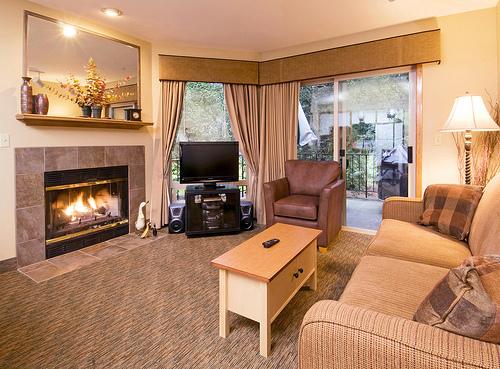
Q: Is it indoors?
A: Yes, it is indoors.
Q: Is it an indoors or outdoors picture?
A: It is indoors.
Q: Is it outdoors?
A: No, it is indoors.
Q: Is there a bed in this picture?
A: No, there are no beds.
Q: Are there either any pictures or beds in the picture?
A: No, there are no beds or pictures.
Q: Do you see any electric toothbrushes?
A: No, there are no electric toothbrushes.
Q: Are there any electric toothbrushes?
A: No, there are no electric toothbrushes.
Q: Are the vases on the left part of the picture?
A: Yes, the vases are on the left of the image.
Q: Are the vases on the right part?
A: No, the vases are on the left of the image.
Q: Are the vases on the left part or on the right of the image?
A: The vases are on the left of the image.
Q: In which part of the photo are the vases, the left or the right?
A: The vases are on the left of the image.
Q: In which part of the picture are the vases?
A: The vases are on the left of the image.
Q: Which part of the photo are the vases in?
A: The vases are on the left of the image.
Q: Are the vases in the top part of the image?
A: Yes, the vases are in the top of the image.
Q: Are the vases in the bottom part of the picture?
A: No, the vases are in the top of the image.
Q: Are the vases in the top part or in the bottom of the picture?
A: The vases are in the top of the image.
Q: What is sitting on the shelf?
A: The vases are sitting on the shelf.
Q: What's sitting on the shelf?
A: The vases are sitting on the shelf.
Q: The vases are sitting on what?
A: The vases are sitting on the shelf.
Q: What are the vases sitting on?
A: The vases are sitting on the shelf.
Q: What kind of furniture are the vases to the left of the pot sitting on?
A: The vases are sitting on the shelf.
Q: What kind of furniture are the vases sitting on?
A: The vases are sitting on the shelf.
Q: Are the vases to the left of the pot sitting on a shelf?
A: Yes, the vases are sitting on a shelf.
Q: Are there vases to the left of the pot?
A: Yes, there are vases to the left of the pot.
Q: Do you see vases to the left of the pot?
A: Yes, there are vases to the left of the pot.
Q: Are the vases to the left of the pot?
A: Yes, the vases are to the left of the pot.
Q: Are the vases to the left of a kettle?
A: No, the vases are to the left of the pot.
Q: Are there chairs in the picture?
A: Yes, there is a chair.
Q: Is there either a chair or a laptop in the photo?
A: Yes, there is a chair.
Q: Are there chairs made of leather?
A: Yes, there is a chair that is made of leather.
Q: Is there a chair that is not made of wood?
A: Yes, there is a chair that is made of leather.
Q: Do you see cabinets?
A: No, there are no cabinets.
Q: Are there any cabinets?
A: No, there are no cabinets.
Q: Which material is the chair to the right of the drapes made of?
A: The chair is made of leather.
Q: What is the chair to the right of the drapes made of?
A: The chair is made of leather.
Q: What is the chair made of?
A: The chair is made of leather.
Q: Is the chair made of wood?
A: No, the chair is made of leather.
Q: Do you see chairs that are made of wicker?
A: No, there is a chair but it is made of leather.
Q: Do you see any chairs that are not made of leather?
A: No, there is a chair but it is made of leather.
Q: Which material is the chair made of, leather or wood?
A: The chair is made of leather.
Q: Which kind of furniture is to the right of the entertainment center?
A: The piece of furniture is a chair.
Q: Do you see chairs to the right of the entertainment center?
A: Yes, there is a chair to the right of the entertainment center.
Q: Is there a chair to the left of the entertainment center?
A: No, the chair is to the right of the entertainment center.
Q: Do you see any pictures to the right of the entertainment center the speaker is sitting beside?
A: No, there is a chair to the right of the entertainment center.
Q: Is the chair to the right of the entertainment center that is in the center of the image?
A: Yes, the chair is to the right of the entertainment center.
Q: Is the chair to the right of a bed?
A: No, the chair is to the right of the entertainment center.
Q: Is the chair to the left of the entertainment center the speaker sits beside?
A: No, the chair is to the right of the entertainment center.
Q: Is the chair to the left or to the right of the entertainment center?
A: The chair is to the right of the entertainment center.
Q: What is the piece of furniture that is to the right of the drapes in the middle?
A: The piece of furniture is a chair.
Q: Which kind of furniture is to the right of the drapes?
A: The piece of furniture is a chair.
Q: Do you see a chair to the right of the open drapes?
A: Yes, there is a chair to the right of the drapes.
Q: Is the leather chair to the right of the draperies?
A: Yes, the chair is to the right of the draperies.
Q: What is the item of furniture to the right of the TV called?
A: The piece of furniture is a chair.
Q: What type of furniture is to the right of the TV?
A: The piece of furniture is a chair.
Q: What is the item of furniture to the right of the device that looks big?
A: The piece of furniture is a chair.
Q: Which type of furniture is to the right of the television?
A: The piece of furniture is a chair.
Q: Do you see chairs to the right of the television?
A: Yes, there is a chair to the right of the television.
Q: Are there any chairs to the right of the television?
A: Yes, there is a chair to the right of the television.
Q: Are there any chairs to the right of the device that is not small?
A: Yes, there is a chair to the right of the television.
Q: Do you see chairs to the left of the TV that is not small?
A: No, the chair is to the right of the TV.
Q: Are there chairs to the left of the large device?
A: No, the chair is to the right of the TV.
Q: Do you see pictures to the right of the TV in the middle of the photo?
A: No, there is a chair to the right of the TV.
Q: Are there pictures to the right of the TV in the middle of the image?
A: No, there is a chair to the right of the TV.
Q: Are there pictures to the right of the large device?
A: No, there is a chair to the right of the TV.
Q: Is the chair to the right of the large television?
A: Yes, the chair is to the right of the TV.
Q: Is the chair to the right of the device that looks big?
A: Yes, the chair is to the right of the TV.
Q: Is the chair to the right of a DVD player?
A: No, the chair is to the right of the TV.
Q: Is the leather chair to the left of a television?
A: No, the chair is to the right of a television.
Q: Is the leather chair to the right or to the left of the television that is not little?
A: The chair is to the right of the television.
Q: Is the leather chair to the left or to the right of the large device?
A: The chair is to the right of the television.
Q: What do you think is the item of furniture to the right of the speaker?
A: The piece of furniture is a chair.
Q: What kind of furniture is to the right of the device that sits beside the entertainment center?
A: The piece of furniture is a chair.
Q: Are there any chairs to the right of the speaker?
A: Yes, there is a chair to the right of the speaker.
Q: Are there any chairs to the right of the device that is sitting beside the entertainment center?
A: Yes, there is a chair to the right of the speaker.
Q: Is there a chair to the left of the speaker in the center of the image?
A: No, the chair is to the right of the speaker.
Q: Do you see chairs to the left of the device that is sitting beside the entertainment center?
A: No, the chair is to the right of the speaker.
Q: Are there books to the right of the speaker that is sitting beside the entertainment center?
A: No, there is a chair to the right of the speaker.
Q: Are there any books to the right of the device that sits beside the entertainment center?
A: No, there is a chair to the right of the speaker.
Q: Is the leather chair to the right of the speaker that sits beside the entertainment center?
A: Yes, the chair is to the right of the speaker.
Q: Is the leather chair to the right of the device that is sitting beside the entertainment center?
A: Yes, the chair is to the right of the speaker.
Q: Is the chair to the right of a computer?
A: No, the chair is to the right of the speaker.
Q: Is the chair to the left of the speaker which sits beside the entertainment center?
A: No, the chair is to the right of the speaker.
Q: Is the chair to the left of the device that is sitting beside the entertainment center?
A: No, the chair is to the right of the speaker.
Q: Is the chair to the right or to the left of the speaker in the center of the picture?
A: The chair is to the right of the speaker.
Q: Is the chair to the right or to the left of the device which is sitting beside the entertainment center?
A: The chair is to the right of the speaker.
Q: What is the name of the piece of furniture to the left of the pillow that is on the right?
A: The piece of furniture is a chair.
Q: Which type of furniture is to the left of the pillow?
A: The piece of furniture is a chair.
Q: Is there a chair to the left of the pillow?
A: Yes, there is a chair to the left of the pillow.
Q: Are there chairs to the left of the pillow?
A: Yes, there is a chair to the left of the pillow.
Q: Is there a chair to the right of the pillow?
A: No, the chair is to the left of the pillow.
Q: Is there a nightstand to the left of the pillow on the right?
A: No, there is a chair to the left of the pillow.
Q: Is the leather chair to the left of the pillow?
A: Yes, the chair is to the left of the pillow.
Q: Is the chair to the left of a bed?
A: No, the chair is to the left of the pillow.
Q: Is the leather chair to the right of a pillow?
A: No, the chair is to the left of a pillow.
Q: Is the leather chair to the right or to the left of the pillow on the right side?
A: The chair is to the left of the pillow.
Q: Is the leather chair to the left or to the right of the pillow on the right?
A: The chair is to the left of the pillow.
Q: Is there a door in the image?
A: Yes, there are doors.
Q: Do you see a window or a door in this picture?
A: Yes, there are doors.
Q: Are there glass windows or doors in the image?
A: Yes, there are glass doors.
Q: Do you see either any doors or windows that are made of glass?
A: Yes, the doors are made of glass.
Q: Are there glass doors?
A: Yes, there are doors that are made of glass.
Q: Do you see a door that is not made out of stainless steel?
A: Yes, there are doors that are made of glass.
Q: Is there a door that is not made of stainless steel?
A: Yes, there are doors that are made of glass.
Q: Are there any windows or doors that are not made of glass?
A: No, there are doors but they are made of glass.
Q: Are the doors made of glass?
A: Yes, the doors are made of glass.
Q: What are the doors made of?
A: The doors are made of glass.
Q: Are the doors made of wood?
A: No, the doors are made of glass.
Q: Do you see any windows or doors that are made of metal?
A: No, there are doors but they are made of glass.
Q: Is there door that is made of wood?
A: No, there are doors but they are made of glass.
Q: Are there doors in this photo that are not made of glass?
A: No, there are doors but they are made of glass.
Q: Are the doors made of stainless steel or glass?
A: The doors are made of glass.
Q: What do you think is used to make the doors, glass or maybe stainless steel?
A: The doors are made of glass.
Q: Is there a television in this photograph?
A: Yes, there is a television.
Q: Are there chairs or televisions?
A: Yes, there is a television.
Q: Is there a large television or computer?
A: Yes, there is a large television.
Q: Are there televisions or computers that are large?
A: Yes, the television is large.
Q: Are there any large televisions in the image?
A: Yes, there is a large television.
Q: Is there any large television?
A: Yes, there is a large television.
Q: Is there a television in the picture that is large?
A: Yes, there is a television that is large.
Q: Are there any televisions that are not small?
A: Yes, there is a large television.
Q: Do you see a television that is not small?
A: Yes, there is a large television.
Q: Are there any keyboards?
A: No, there are no keyboards.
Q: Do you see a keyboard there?
A: No, there are no keyboards.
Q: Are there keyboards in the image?
A: No, there are no keyboards.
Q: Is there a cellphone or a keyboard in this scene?
A: No, there are no keyboards or cell phones.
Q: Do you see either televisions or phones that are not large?
A: No, there is a television but it is large.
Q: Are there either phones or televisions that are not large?
A: No, there is a television but it is large.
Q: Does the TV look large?
A: Yes, the TV is large.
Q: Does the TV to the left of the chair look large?
A: Yes, the television is large.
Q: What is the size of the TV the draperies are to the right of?
A: The TV is large.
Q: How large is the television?
A: The television is large.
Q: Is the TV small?
A: No, the TV is large.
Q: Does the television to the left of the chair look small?
A: No, the TV is large.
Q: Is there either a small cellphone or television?
A: No, there is a television but it is large.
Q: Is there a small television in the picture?
A: No, there is a television but it is large.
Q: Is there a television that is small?
A: No, there is a television but it is large.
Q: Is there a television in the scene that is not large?
A: No, there is a television but it is large.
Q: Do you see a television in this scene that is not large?
A: No, there is a television but it is large.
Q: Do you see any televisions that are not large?
A: No, there is a television but it is large.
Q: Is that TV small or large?
A: The TV is large.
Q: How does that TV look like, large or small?
A: The TV is large.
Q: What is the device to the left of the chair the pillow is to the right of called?
A: The device is a television.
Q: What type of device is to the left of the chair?
A: The device is a television.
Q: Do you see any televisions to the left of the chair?
A: Yes, there is a television to the left of the chair.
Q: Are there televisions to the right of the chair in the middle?
A: No, the television is to the left of the chair.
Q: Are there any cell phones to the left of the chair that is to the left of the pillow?
A: No, there is a television to the left of the chair.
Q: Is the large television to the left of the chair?
A: Yes, the television is to the left of the chair.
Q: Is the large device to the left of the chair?
A: Yes, the television is to the left of the chair.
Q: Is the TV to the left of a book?
A: No, the TV is to the left of the chair.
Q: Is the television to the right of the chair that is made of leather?
A: No, the television is to the left of the chair.